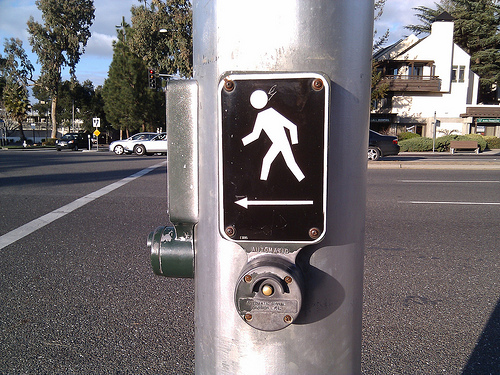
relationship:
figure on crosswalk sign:
[240, 90, 304, 182] [217, 73, 330, 243]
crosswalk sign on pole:
[217, 70, 331, 247] [190, 0, 372, 371]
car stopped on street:
[54, 130, 92, 150] [5, 145, 485, 358]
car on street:
[130, 134, 165, 157] [5, 145, 485, 358]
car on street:
[110, 129, 162, 157] [5, 145, 485, 358]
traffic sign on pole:
[93, 128, 100, 138] [94, 114, 98, 151]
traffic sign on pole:
[91, 117, 99, 127] [94, 114, 98, 151]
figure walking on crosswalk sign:
[241, 89, 306, 182] [217, 73, 330, 243]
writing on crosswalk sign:
[262, 79, 283, 103] [217, 73, 330, 243]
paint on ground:
[2, 151, 142, 253] [10, 147, 445, 354]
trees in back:
[10, 1, 192, 146] [14, 5, 484, 162]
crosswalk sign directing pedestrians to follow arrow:
[217, 73, 330, 243] [234, 192, 316, 206]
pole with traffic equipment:
[190, 0, 372, 371] [148, 68, 333, 331]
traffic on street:
[52, 108, 162, 171] [5, 145, 485, 358]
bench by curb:
[446, 136, 483, 157] [373, 162, 484, 166]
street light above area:
[156, 23, 173, 39] [15, 90, 170, 177]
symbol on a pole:
[236, 88, 308, 189] [190, 0, 372, 371]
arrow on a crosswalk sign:
[233, 196, 313, 209] [217, 70, 331, 247]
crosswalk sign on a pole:
[217, 73, 330, 243] [190, 0, 372, 371]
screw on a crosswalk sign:
[311, 74, 329, 94] [217, 73, 330, 243]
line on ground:
[0, 159, 167, 249] [0, 160, 139, 368]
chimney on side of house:
[428, 14, 458, 94] [384, 15, 482, 139]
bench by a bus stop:
[446, 136, 483, 157] [395, 129, 485, 169]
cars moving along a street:
[53, 123, 167, 159] [5, 145, 485, 358]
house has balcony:
[363, 14, 489, 157] [373, 65, 450, 103]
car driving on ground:
[124, 132, 167, 155] [0, 160, 139, 368]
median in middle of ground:
[363, 145, 486, 177] [0, 160, 139, 368]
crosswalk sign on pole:
[217, 73, 330, 243] [125, 0, 379, 373]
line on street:
[0, 133, 170, 268] [0, 141, 493, 373]